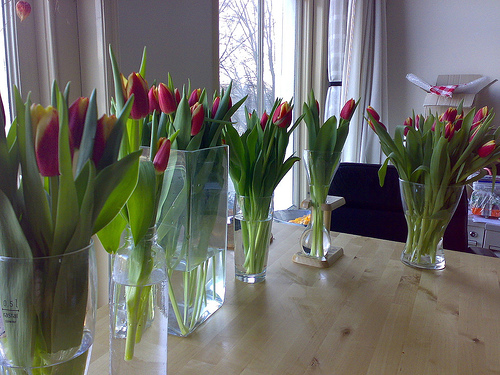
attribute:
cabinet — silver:
[456, 174, 498, 252]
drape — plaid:
[325, 0, 345, 97]